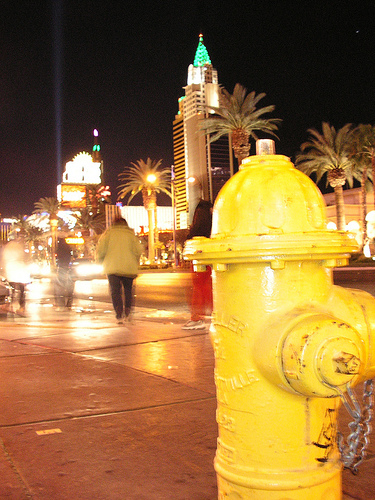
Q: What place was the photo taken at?
A: It was taken at the sidewalk.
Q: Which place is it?
A: It is a sidewalk.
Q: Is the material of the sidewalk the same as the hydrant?
A: No, the sidewalk is made of concrete and the hydrant is made of metal.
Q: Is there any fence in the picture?
A: No, there are no fences.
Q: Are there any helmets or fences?
A: No, there are no fences or helmets.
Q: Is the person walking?
A: Yes, the person is walking.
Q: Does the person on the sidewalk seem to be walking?
A: Yes, the person is walking.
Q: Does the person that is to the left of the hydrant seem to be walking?
A: Yes, the person is walking.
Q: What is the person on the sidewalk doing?
A: The person is walking.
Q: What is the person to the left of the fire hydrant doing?
A: The person is walking.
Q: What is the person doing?
A: The person is walking.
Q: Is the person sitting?
A: No, the person is walking.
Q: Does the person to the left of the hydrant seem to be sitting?
A: No, the person is walking.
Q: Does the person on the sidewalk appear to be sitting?
A: No, the person is walking.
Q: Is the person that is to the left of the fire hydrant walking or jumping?
A: The person is walking.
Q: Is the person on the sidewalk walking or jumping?
A: The person is walking.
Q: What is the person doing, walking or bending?
A: The person is walking.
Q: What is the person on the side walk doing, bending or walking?
A: The person is walking.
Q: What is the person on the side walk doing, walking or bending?
A: The person is walking.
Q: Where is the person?
A: The person is on the sidewalk.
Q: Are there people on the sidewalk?
A: Yes, there is a person on the sidewalk.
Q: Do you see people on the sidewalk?
A: Yes, there is a person on the sidewalk.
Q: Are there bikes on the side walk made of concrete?
A: No, there is a person on the sidewalk.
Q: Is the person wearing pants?
A: Yes, the person is wearing pants.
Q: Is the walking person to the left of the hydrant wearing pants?
A: Yes, the person is wearing pants.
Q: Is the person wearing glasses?
A: No, the person is wearing pants.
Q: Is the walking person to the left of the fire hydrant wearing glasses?
A: No, the person is wearing pants.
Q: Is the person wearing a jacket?
A: Yes, the person is wearing a jacket.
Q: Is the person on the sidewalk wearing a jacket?
A: Yes, the person is wearing a jacket.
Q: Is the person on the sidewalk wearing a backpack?
A: No, the person is wearing a jacket.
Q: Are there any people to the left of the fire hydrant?
A: Yes, there is a person to the left of the fire hydrant.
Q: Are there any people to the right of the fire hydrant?
A: No, the person is to the left of the fire hydrant.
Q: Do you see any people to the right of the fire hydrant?
A: No, the person is to the left of the fire hydrant.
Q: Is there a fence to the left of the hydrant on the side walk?
A: No, there is a person to the left of the hydrant.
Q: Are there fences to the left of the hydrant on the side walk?
A: No, there is a person to the left of the hydrant.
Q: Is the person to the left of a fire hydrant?
A: Yes, the person is to the left of a fire hydrant.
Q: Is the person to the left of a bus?
A: No, the person is to the left of a fire hydrant.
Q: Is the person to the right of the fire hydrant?
A: No, the person is to the left of the fire hydrant.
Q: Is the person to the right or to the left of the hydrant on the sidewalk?
A: The person is to the left of the hydrant.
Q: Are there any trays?
A: No, there are no trays.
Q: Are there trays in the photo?
A: No, there are no trays.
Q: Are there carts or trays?
A: No, there are no trays or carts.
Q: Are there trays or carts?
A: No, there are no trays or carts.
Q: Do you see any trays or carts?
A: No, there are no trays or carts.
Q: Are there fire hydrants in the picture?
A: Yes, there is a fire hydrant.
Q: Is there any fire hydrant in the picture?
A: Yes, there is a fire hydrant.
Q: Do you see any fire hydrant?
A: Yes, there is a fire hydrant.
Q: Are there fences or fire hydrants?
A: Yes, there is a fire hydrant.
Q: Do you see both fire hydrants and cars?
A: No, there is a fire hydrant but no cars.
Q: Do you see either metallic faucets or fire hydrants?
A: Yes, there is a metal fire hydrant.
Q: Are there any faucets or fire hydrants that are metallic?
A: Yes, the fire hydrant is metallic.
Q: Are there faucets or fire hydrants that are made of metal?
A: Yes, the fire hydrant is made of metal.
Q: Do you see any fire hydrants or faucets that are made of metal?
A: Yes, the fire hydrant is made of metal.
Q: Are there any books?
A: No, there are no books.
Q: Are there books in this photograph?
A: No, there are no books.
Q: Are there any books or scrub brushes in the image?
A: No, there are no books or scrub brushes.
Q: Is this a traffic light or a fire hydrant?
A: This is a fire hydrant.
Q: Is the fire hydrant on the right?
A: Yes, the fire hydrant is on the right of the image.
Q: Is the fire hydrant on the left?
A: No, the fire hydrant is on the right of the image.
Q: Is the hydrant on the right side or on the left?
A: The hydrant is on the right of the image.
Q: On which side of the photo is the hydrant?
A: The hydrant is on the right of the image.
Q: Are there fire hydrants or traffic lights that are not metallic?
A: No, there is a fire hydrant but it is metallic.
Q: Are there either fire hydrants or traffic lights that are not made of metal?
A: No, there is a fire hydrant but it is made of metal.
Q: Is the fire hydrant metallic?
A: Yes, the fire hydrant is metallic.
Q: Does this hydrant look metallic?
A: Yes, the hydrant is metallic.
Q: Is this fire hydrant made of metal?
A: Yes, the fire hydrant is made of metal.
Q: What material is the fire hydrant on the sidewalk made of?
A: The hydrant is made of metal.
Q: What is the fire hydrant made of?
A: The hydrant is made of metal.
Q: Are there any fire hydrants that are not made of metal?
A: No, there is a fire hydrant but it is made of metal.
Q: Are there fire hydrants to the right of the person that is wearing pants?
A: Yes, there is a fire hydrant to the right of the person.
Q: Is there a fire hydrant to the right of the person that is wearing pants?
A: Yes, there is a fire hydrant to the right of the person.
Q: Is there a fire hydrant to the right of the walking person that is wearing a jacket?
A: Yes, there is a fire hydrant to the right of the person.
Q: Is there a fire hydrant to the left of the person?
A: No, the fire hydrant is to the right of the person.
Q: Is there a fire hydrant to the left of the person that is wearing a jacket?
A: No, the fire hydrant is to the right of the person.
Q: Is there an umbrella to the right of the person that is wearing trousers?
A: No, there is a fire hydrant to the right of the person.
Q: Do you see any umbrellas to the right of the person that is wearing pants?
A: No, there is a fire hydrant to the right of the person.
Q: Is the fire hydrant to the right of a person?
A: Yes, the fire hydrant is to the right of a person.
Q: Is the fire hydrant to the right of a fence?
A: No, the fire hydrant is to the right of a person.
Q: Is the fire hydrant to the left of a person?
A: No, the fire hydrant is to the right of a person.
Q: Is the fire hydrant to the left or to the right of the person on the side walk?
A: The fire hydrant is to the right of the person.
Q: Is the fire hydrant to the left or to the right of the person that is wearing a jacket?
A: The fire hydrant is to the right of the person.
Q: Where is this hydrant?
A: The hydrant is on the sidewalk.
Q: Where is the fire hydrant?
A: The hydrant is on the sidewalk.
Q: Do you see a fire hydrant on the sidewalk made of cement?
A: Yes, there is a fire hydrant on the sidewalk.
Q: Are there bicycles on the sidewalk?
A: No, there is a fire hydrant on the sidewalk.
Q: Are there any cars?
A: No, there are no cars.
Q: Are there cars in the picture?
A: No, there are no cars.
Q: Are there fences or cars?
A: No, there are no cars or fences.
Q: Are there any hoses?
A: No, there are no hoses.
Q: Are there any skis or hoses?
A: No, there are no hoses or skis.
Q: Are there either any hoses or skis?
A: No, there are no hoses or skis.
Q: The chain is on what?
A: The chain is on the hydrant.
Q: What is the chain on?
A: The chain is on the hydrant.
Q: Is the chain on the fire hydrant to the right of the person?
A: Yes, the chain is on the hydrant.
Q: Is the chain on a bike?
A: No, the chain is on the hydrant.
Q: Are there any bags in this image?
A: No, there are no bags.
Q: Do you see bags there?
A: No, there are no bags.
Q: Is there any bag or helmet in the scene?
A: No, there are no bags or helmets.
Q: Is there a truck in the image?
A: No, there are no trucks.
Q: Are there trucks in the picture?
A: No, there are no trucks.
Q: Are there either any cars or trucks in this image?
A: No, there are no trucks or cars.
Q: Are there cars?
A: No, there are no cars.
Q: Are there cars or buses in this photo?
A: No, there are no cars or buses.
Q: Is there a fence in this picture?
A: No, there are no fences.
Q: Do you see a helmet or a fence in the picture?
A: No, there are no fences or helmets.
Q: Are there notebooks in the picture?
A: No, there are no notebooks.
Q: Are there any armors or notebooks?
A: No, there are no notebooks or armors.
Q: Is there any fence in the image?
A: No, there are no fences.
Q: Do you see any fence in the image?
A: No, there are no fences.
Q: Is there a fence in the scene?
A: No, there are no fences.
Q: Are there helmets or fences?
A: No, there are no fences or helmets.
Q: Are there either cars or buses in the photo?
A: No, there are no cars or buses.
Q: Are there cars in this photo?
A: No, there are no cars.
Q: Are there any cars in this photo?
A: No, there are no cars.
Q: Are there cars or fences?
A: No, there are no cars or fences.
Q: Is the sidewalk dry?
A: Yes, the sidewalk is dry.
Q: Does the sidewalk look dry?
A: Yes, the sidewalk is dry.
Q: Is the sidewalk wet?
A: No, the sidewalk is dry.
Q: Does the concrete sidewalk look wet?
A: No, the sidewalk is dry.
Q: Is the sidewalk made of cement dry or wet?
A: The side walk is dry.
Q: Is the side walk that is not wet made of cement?
A: Yes, the side walk is made of cement.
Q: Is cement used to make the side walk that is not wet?
A: Yes, the side walk is made of cement.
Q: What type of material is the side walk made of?
A: The side walk is made of concrete.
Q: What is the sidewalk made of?
A: The side walk is made of concrete.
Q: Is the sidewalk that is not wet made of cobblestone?
A: No, the sidewalk is made of cement.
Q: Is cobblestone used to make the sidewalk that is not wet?
A: No, the sidewalk is made of cement.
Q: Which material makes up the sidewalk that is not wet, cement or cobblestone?
A: The sidewalk is made of cement.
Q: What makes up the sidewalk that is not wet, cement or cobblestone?
A: The sidewalk is made of cement.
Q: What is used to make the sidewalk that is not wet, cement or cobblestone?
A: The sidewalk is made of cement.